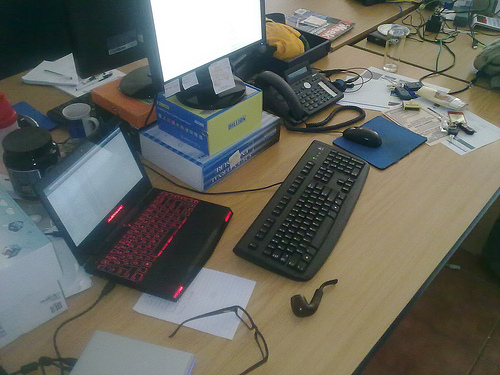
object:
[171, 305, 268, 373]
glasses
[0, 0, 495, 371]
desk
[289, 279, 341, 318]
pipe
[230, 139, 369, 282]
keyboard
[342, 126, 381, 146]
mouse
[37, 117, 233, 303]
laptop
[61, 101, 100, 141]
cup